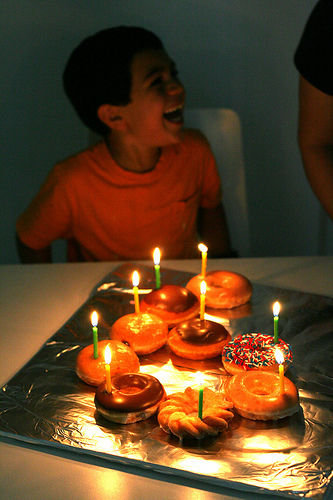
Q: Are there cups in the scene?
A: No, there are no cups.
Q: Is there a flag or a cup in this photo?
A: No, there are no cups or flags.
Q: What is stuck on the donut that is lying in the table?
A: The candle is stuck on the doughnut.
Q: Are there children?
A: Yes, there is a child.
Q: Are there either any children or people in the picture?
A: Yes, there is a child.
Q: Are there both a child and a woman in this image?
A: No, there is a child but no women.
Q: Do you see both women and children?
A: No, there is a child but no women.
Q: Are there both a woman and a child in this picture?
A: No, there is a child but no women.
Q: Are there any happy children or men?
A: Yes, there is a happy child.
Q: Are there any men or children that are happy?
A: Yes, the child is happy.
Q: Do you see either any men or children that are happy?
A: Yes, the child is happy.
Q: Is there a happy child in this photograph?
A: Yes, there is a happy child.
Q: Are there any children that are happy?
A: Yes, there is a child that is happy.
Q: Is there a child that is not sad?
A: Yes, there is a happy child.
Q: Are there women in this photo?
A: No, there are no women.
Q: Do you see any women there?
A: No, there are no women.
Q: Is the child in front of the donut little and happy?
A: Yes, the kid is little and happy.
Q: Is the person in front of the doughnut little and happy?
A: Yes, the kid is little and happy.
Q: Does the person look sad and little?
A: No, the child is little but happy.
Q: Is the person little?
A: Yes, the kid is little.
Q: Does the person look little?
A: Yes, the kid is little.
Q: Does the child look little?
A: Yes, the child is little.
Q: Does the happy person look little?
A: Yes, the child is little.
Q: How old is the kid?
A: The kid is little.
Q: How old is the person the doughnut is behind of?
A: The kid is little.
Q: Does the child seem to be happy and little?
A: Yes, the child is happy and little.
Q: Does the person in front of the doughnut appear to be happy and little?
A: Yes, the child is happy and little.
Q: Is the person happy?
A: Yes, the child is happy.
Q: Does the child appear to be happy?
A: Yes, the child is happy.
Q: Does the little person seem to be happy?
A: Yes, the child is happy.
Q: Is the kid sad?
A: No, the kid is happy.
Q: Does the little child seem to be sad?
A: No, the kid is happy.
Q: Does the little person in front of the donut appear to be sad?
A: No, the kid is happy.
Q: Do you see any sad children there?
A: No, there is a child but he is happy.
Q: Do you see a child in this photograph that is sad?
A: No, there is a child but he is happy.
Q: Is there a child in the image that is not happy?
A: No, there is a child but he is happy.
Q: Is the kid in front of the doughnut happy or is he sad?
A: The kid is happy.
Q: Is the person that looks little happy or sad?
A: The kid is happy.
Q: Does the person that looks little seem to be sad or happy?
A: The kid is happy.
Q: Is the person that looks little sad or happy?
A: The kid is happy.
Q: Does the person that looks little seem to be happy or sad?
A: The kid is happy.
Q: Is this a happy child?
A: Yes, this is a happy child.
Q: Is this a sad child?
A: No, this is a happy child.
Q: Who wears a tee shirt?
A: The kid wears a tee shirt.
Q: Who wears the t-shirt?
A: The kid wears a tee shirt.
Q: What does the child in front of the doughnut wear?
A: The child wears a tshirt.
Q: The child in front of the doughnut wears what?
A: The child wears a tshirt.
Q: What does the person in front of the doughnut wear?
A: The child wears a tshirt.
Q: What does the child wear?
A: The child wears a tshirt.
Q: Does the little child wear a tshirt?
A: Yes, the kid wears a tshirt.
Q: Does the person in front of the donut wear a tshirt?
A: Yes, the kid wears a tshirt.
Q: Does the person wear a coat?
A: No, the kid wears a tshirt.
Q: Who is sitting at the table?
A: The child is sitting at the table.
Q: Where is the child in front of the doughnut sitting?
A: The child is sitting at the table.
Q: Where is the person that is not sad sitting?
A: The child is sitting at the table.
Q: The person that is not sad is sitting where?
A: The child is sitting at the table.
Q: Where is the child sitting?
A: The child is sitting at the table.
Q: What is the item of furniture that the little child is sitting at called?
A: The piece of furniture is a table.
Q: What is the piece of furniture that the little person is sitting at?
A: The piece of furniture is a table.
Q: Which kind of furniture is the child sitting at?
A: The kid is sitting at the table.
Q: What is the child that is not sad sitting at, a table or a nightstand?
A: The kid is sitting at a table.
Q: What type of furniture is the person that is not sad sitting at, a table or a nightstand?
A: The kid is sitting at a table.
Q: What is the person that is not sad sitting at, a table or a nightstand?
A: The kid is sitting at a table.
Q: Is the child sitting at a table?
A: Yes, the child is sitting at a table.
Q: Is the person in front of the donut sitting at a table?
A: Yes, the child is sitting at a table.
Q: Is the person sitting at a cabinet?
A: No, the kid is sitting at a table.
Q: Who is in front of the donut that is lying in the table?
A: The kid is in front of the donut.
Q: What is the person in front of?
A: The kid is in front of the donut.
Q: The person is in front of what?
A: The kid is in front of the donut.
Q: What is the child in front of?
A: The kid is in front of the donut.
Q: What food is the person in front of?
A: The kid is in front of the donut.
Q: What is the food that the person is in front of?
A: The food is a donut.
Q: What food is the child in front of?
A: The kid is in front of the donut.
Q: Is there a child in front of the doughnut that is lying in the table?
A: Yes, there is a child in front of the doughnut.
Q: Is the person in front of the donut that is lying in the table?
A: Yes, the kid is in front of the doughnut.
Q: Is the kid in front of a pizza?
A: No, the kid is in front of the doughnut.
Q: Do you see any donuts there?
A: Yes, there is a donut.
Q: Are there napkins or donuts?
A: Yes, there is a donut.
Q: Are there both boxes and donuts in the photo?
A: No, there is a donut but no boxes.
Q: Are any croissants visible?
A: No, there are no croissants.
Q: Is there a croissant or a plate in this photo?
A: No, there are no croissants or plates.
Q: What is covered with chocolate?
A: The donut is covered with chocolate.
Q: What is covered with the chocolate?
A: The donut is covered with chocolate.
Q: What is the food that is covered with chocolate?
A: The food is a donut.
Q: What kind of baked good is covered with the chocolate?
A: The food is a donut.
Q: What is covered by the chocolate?
A: The doughnut is covered by the chocolate.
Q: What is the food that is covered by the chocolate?
A: The food is a donut.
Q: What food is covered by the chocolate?
A: The food is a donut.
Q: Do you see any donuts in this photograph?
A: Yes, there is a donut.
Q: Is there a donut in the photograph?
A: Yes, there is a donut.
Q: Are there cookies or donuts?
A: Yes, there is a donut.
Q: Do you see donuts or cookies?
A: Yes, there is a donut.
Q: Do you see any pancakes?
A: No, there are no pancakes.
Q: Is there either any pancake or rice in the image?
A: No, there are no pancakes or rice.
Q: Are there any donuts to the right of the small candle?
A: Yes, there is a donut to the right of the candle.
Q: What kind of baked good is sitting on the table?
A: The food is a donut.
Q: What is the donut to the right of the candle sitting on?
A: The donut is sitting on the table.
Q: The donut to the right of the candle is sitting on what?
A: The donut is sitting on the table.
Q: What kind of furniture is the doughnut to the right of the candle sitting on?
A: The donut is sitting on the table.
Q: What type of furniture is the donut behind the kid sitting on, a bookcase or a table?
A: The doughnut is sitting on a table.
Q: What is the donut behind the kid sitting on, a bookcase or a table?
A: The doughnut is sitting on a table.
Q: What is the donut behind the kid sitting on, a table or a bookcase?
A: The doughnut is sitting on a table.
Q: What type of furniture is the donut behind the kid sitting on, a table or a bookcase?
A: The doughnut is sitting on a table.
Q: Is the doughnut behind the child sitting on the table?
A: Yes, the donut is sitting on the table.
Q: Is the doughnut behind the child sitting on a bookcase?
A: No, the donut is sitting on the table.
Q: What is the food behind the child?
A: The food is a donut.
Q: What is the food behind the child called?
A: The food is a donut.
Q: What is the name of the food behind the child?
A: The food is a donut.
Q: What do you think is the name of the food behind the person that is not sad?
A: The food is a donut.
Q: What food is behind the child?
A: The food is a donut.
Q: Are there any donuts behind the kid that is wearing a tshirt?
A: Yes, there is a donut behind the kid.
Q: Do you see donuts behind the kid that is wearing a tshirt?
A: Yes, there is a donut behind the kid.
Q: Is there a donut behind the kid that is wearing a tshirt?
A: Yes, there is a donut behind the kid.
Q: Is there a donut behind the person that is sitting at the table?
A: Yes, there is a donut behind the kid.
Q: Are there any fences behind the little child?
A: No, there is a donut behind the child.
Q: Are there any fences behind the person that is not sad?
A: No, there is a donut behind the child.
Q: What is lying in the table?
A: The donut is lying in the table.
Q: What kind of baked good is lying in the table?
A: The food is a donut.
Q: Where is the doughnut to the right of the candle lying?
A: The donut is lying in the table.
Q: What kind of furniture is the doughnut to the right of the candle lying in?
A: The donut is lying in the table.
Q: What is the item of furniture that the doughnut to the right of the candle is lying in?
A: The piece of furniture is a table.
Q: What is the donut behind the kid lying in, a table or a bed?
A: The donut is lying in a table.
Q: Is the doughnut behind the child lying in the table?
A: Yes, the doughnut is lying in the table.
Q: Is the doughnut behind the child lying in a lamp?
A: No, the donut is lying in the table.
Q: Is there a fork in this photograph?
A: No, there are no forks.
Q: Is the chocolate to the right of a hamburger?
A: No, the chocolate is to the right of a donut.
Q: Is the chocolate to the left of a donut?
A: No, the chocolate is to the right of a donut.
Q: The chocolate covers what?
A: The chocolate covers the donut.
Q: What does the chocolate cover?
A: The chocolate covers the donut.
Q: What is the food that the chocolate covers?
A: The food is a donut.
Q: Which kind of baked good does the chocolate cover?
A: The chocolate covers the doughnut.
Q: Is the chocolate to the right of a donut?
A: No, the chocolate is to the left of a donut.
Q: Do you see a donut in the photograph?
A: Yes, there is a donut.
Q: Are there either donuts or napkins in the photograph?
A: Yes, there is a donut.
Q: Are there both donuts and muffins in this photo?
A: No, there is a donut but no muffins.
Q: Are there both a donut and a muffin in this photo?
A: No, there is a donut but no muffins.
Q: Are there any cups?
A: No, there are no cups.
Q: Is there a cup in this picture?
A: No, there are no cups.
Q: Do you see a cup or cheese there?
A: No, there are no cups or cheese.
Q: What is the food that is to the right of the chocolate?
A: The food is a donut.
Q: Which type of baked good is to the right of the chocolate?
A: The food is a donut.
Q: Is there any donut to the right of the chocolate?
A: Yes, there is a donut to the right of the chocolate.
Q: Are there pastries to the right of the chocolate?
A: No, there is a donut to the right of the chocolate.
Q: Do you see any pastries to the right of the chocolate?
A: No, there is a donut to the right of the chocolate.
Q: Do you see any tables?
A: Yes, there is a table.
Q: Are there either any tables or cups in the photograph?
A: Yes, there is a table.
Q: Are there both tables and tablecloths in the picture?
A: No, there is a table but no tablecloths.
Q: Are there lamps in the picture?
A: No, there are no lamps.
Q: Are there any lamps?
A: No, there are no lamps.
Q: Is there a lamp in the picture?
A: No, there are no lamps.